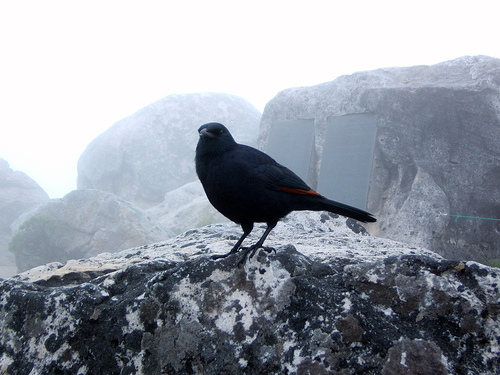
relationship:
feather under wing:
[275, 186, 322, 197] [243, 147, 322, 195]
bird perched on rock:
[194, 123, 378, 259] [2, 208, 498, 374]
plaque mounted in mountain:
[264, 117, 318, 193] [250, 54, 499, 268]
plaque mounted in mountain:
[318, 114, 375, 212] [250, 54, 499, 268]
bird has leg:
[194, 123, 378, 259] [211, 221, 255, 259]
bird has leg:
[194, 123, 378, 259] [237, 222, 278, 260]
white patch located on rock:
[122, 304, 146, 333] [2, 208, 498, 374]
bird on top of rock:
[194, 123, 378, 259] [2, 208, 498, 374]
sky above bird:
[0, 1, 500, 202] [194, 123, 378, 259]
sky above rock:
[0, 1, 500, 202] [2, 208, 498, 374]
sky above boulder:
[0, 1, 500, 202] [8, 186, 172, 269]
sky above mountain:
[0, 1, 500, 202] [250, 54, 499, 268]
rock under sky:
[2, 208, 498, 374] [0, 1, 500, 202]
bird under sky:
[194, 123, 378, 259] [0, 1, 500, 202]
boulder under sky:
[8, 186, 172, 269] [0, 1, 500, 202]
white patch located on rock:
[245, 257, 290, 299] [2, 208, 498, 374]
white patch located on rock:
[339, 296, 353, 315] [2, 208, 498, 374]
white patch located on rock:
[291, 346, 308, 366] [2, 208, 498, 374]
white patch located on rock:
[422, 268, 438, 309] [2, 208, 498, 374]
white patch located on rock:
[126, 349, 146, 374] [2, 208, 498, 374]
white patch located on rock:
[102, 275, 116, 291] [2, 208, 498, 374]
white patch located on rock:
[464, 259, 490, 270] [2, 208, 498, 374]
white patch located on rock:
[213, 307, 239, 335] [2, 208, 498, 374]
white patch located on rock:
[397, 352, 410, 369] [2, 208, 498, 374]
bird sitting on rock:
[194, 123, 378, 259] [2, 208, 498, 374]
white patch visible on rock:
[245, 257, 290, 299] [2, 208, 498, 374]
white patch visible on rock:
[102, 275, 116, 291] [2, 208, 498, 374]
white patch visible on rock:
[122, 304, 146, 333] [2, 208, 498, 374]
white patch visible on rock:
[126, 349, 146, 374] [2, 208, 498, 374]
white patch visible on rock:
[464, 259, 490, 270] [2, 208, 498, 374]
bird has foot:
[194, 123, 378, 259] [240, 244, 266, 261]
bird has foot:
[194, 123, 378, 259] [210, 253, 228, 262]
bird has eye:
[194, 123, 378, 259] [210, 127, 222, 136]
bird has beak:
[194, 123, 378, 259] [197, 129, 209, 139]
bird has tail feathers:
[194, 123, 378, 259] [299, 195, 375, 227]